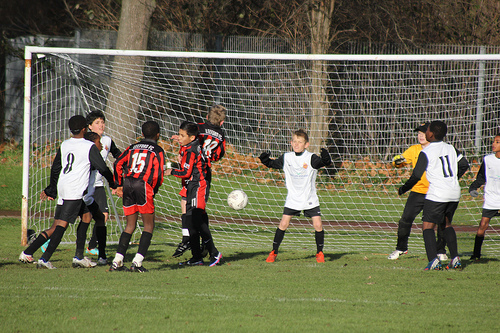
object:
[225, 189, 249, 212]
soccer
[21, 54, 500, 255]
net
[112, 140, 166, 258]
uniform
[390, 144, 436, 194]
shirt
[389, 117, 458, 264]
goalie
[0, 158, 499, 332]
grass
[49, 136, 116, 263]
uniform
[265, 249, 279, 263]
shoes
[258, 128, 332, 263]
boy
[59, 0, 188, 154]
trees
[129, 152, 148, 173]
15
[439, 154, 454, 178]
11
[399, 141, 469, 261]
uniform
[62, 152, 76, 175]
8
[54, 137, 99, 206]
jersey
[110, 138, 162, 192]
jersey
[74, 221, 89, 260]
cleats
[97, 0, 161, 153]
trunk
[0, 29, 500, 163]
fence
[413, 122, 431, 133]
hat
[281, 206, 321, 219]
shorts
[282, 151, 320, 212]
shirt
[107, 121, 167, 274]
boys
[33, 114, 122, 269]
boys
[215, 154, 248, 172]
leaves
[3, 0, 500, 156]
background